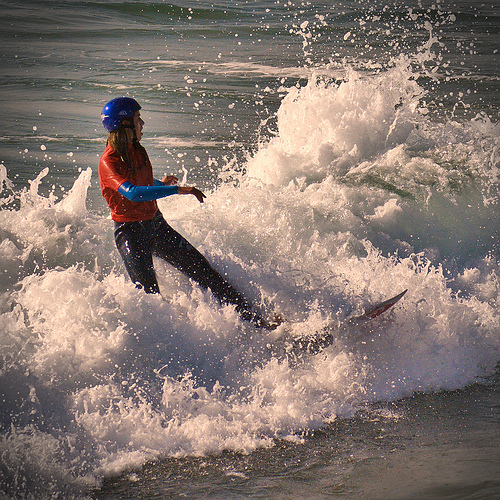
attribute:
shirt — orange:
[95, 145, 163, 224]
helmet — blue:
[91, 95, 151, 131]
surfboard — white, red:
[283, 279, 425, 384]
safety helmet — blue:
[79, 93, 180, 154]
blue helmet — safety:
[74, 86, 177, 157]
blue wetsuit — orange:
[113, 208, 292, 346]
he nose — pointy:
[137, 117, 151, 129]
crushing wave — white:
[48, 62, 495, 361]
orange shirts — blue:
[80, 133, 173, 226]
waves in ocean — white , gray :
[47, 108, 498, 400]